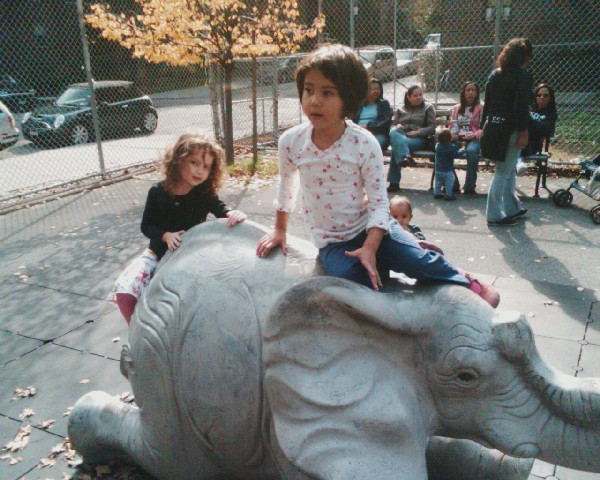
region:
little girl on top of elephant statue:
[58, 43, 598, 479]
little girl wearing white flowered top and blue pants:
[250, 44, 503, 308]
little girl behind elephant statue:
[67, 128, 598, 479]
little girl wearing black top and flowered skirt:
[101, 128, 250, 324]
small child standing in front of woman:
[429, 80, 484, 200]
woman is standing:
[474, 29, 531, 229]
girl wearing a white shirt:
[281, 124, 387, 231]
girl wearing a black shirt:
[135, 172, 223, 227]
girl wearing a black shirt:
[474, 68, 538, 133]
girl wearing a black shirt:
[529, 104, 553, 143]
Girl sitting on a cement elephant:
[240, 53, 513, 331]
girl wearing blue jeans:
[321, 225, 474, 299]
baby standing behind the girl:
[387, 196, 423, 236]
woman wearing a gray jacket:
[387, 98, 445, 131]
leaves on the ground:
[11, 386, 61, 469]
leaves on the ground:
[35, 206, 119, 279]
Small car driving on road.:
[36, 76, 158, 127]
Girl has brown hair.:
[166, 133, 246, 208]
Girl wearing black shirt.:
[134, 178, 209, 247]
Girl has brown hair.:
[290, 62, 366, 107]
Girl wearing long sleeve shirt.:
[278, 133, 389, 246]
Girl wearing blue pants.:
[347, 224, 459, 302]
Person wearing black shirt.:
[482, 64, 530, 124]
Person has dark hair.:
[399, 85, 431, 113]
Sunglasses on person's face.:
[531, 84, 553, 103]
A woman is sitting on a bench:
[524, 78, 558, 155]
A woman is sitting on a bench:
[438, 80, 483, 194]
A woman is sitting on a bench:
[385, 84, 435, 188]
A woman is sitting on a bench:
[351, 74, 389, 146]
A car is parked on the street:
[21, 78, 159, 147]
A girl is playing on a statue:
[117, 130, 244, 329]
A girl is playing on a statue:
[255, 43, 499, 308]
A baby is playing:
[384, 194, 423, 242]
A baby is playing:
[432, 128, 464, 199]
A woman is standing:
[476, 37, 534, 232]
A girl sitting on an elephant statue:
[256, 44, 499, 311]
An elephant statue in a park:
[70, 218, 598, 476]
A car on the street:
[20, 77, 159, 142]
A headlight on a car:
[50, 111, 67, 129]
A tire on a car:
[68, 119, 90, 144]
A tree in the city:
[80, 0, 324, 141]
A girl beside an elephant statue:
[111, 128, 247, 325]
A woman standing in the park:
[481, 35, 536, 233]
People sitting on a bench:
[350, 75, 560, 206]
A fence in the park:
[238, 41, 598, 165]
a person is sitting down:
[263, 42, 505, 312]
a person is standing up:
[484, 36, 530, 220]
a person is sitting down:
[525, 77, 556, 153]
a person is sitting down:
[442, 84, 484, 197]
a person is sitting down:
[385, 84, 434, 190]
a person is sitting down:
[355, 72, 389, 145]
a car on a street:
[18, 78, 156, 145]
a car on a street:
[354, 37, 396, 79]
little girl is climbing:
[113, 133, 248, 320]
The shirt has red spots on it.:
[276, 132, 396, 239]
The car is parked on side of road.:
[36, 64, 168, 154]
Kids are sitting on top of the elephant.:
[140, 58, 475, 390]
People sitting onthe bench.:
[374, 85, 556, 178]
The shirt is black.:
[136, 185, 228, 233]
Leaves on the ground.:
[9, 378, 93, 478]